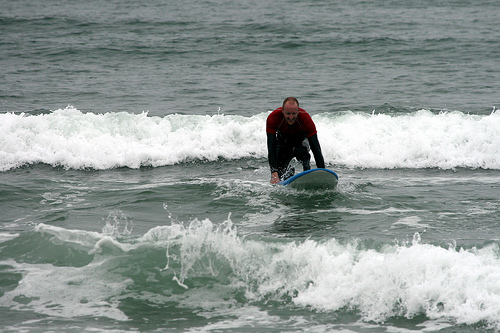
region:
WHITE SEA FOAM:
[319, 252, 354, 285]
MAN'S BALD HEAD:
[277, 96, 302, 123]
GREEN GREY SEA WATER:
[51, 243, 73, 261]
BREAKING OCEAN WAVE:
[6, 115, 250, 155]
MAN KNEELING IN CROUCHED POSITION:
[268, 97, 329, 165]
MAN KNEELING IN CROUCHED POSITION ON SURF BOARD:
[250, 95, 331, 193]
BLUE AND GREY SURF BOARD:
[263, 167, 348, 197]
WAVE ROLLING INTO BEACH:
[103, 226, 440, 323]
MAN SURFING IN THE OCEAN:
[18, 85, 494, 205]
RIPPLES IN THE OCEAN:
[12, 10, 489, 105]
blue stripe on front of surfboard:
[290, 167, 338, 187]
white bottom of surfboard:
[296, 169, 347, 193]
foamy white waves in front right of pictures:
[301, 245, 488, 320]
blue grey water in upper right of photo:
[247, 8, 432, 95]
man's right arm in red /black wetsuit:
[267, 108, 276, 133]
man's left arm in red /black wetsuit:
[298, 107, 330, 144]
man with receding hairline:
[286, 95, 308, 115]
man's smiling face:
[281, 96, 313, 132]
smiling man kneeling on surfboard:
[248, 95, 373, 214]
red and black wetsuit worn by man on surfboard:
[255, 121, 350, 203]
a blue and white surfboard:
[278, 164, 341, 196]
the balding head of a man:
[277, 92, 302, 123]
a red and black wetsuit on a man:
[263, 108, 330, 174]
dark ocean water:
[0, 0, 497, 104]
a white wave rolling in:
[1, 105, 495, 171]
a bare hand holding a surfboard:
[266, 170, 284, 191]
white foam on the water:
[10, 263, 131, 321]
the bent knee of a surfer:
[289, 141, 320, 173]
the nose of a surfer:
[286, 112, 292, 120]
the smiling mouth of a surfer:
[286, 117, 295, 124]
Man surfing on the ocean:
[250, 67, 375, 219]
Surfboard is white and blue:
[260, 136, 394, 232]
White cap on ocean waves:
[197, 225, 334, 303]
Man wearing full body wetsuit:
[261, 82, 346, 258]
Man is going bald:
[279, 85, 312, 140]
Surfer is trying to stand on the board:
[240, 83, 346, 190]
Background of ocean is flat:
[75, 16, 278, 95]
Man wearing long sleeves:
[299, 127, 340, 183]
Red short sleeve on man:
[261, 100, 327, 155]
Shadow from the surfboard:
[285, 178, 386, 248]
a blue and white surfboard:
[250, 154, 372, 216]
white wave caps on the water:
[192, 197, 421, 328]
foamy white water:
[35, 237, 139, 331]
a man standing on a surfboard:
[222, 75, 360, 205]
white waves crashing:
[82, 87, 174, 190]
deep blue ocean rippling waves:
[267, 22, 426, 82]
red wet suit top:
[263, 108, 318, 160]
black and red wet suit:
[255, 85, 331, 190]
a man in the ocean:
[238, 88, 357, 228]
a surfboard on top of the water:
[223, 82, 346, 218]